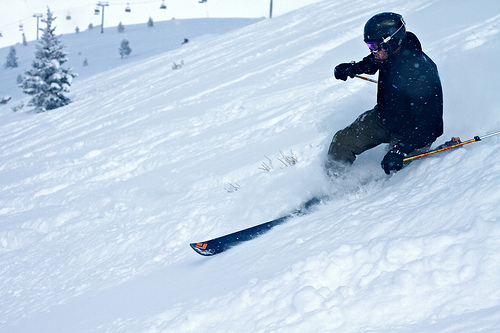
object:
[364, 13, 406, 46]
helmet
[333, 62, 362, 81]
glove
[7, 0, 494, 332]
slope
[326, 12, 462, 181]
man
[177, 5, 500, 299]
ski